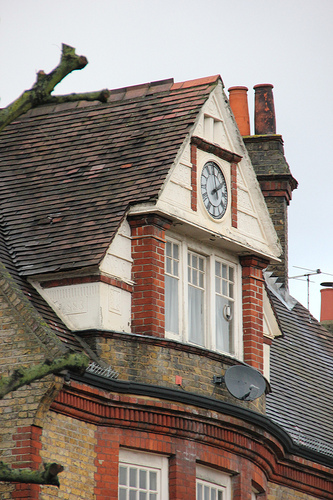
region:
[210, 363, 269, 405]
A black satellite dish.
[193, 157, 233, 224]
A round clock on a building.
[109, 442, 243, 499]
The top portion of two windows.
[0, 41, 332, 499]
A large brick building.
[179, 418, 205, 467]
Discoloration on brick.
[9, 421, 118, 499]
Brown brick in between red brick.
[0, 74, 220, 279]
A multi-colored roof top.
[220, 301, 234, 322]
An object attached to a window.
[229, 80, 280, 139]
Two cylinder shaped cones.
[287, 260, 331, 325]
A large antenna on a roof.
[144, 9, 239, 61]
A clear grey sky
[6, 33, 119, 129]
A dried wooden pole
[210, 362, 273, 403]
A grey satellite dish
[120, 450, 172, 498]
A large white window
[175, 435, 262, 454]
Beautifully arranged red bricks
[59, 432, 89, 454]
Rough brown stone wall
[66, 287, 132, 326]
A crisp white wall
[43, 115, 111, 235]
A long sloping roof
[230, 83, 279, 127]
Two wide chimney outlets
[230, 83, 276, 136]
clay chimneys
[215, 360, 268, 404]
modern satellite dish mounted on old english building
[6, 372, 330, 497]
brick wall that has had repairs done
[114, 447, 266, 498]
windows in a curved wall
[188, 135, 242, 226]
clock in the wall of a building close to the roof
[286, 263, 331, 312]
television antenna mounted on roof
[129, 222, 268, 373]
brickwork on old house that has been replaced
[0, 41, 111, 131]
top of tree that has been badly trimmed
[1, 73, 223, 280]
second story roof of building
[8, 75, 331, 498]
old english house with repaired brickwork and amodern satellite dish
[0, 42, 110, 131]
A green tree branch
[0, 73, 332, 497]
A large stone building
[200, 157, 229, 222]
A clock on the house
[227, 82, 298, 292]
A large stone chimney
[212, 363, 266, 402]
A grey satellite dish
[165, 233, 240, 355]
A large window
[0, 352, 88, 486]
some green tree branches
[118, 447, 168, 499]
A white window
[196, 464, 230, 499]
A white window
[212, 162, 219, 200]
The minute hand of a clock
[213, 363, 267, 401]
A grey satelite dish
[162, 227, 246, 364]
A set of triple windows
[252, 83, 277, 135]
A dirty smoke stack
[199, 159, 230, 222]
An exterior clock face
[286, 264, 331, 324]
A TV antenna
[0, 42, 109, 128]
A cut tree branch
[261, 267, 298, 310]
Aluminium roof flashing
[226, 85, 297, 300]
a brick chimney with terra cotta tops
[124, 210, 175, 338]
A brick column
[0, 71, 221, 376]
A shingled roof top